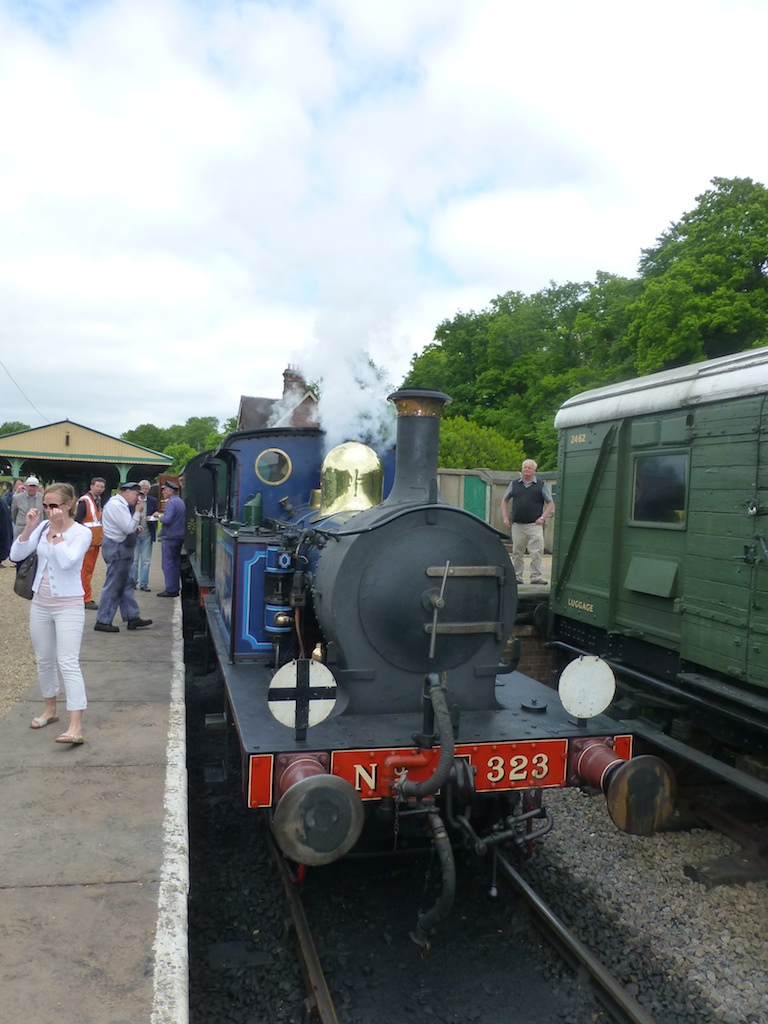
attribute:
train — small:
[570, 386, 754, 625]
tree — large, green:
[467, 317, 525, 369]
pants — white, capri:
[26, 598, 93, 713]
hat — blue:
[119, 475, 135, 497]